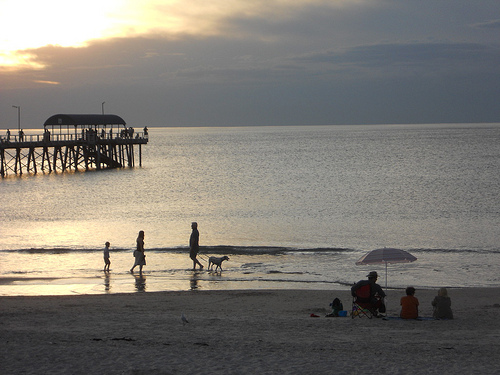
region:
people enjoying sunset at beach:
[73, 151, 461, 347]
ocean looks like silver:
[231, 143, 327, 291]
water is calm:
[238, 144, 477, 261]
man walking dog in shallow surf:
[179, 210, 248, 291]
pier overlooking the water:
[0, 91, 157, 182]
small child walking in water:
[91, 242, 121, 279]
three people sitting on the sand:
[340, 273, 457, 323]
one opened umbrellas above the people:
[342, 232, 453, 314]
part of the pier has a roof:
[47, 110, 127, 137]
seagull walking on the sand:
[171, 306, 206, 333]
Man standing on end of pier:
[140, 116, 154, 146]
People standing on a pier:
[6, 124, 163, 152]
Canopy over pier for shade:
[39, 107, 156, 147]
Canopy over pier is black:
[39, 107, 134, 133]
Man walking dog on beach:
[183, 219, 242, 281]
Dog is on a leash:
[193, 245, 232, 292]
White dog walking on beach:
[202, 253, 230, 275]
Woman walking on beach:
[126, 225, 161, 283]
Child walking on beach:
[91, 235, 123, 282]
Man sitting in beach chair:
[346, 221, 403, 337]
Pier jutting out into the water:
[1, 104, 159, 181]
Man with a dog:
[176, 211, 241, 286]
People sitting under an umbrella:
[292, 234, 467, 334]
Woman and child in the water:
[88, 215, 158, 292]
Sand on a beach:
[41, 293, 318, 365]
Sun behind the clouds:
[4, 5, 206, 112]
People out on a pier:
[50, 114, 160, 157]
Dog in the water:
[202, 249, 242, 279]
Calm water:
[179, 131, 463, 218]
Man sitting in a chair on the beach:
[342, 267, 391, 331]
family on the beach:
[296, 240, 488, 340]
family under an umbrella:
[316, 246, 481, 334]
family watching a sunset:
[301, 239, 461, 330]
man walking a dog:
[182, 216, 233, 291]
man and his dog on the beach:
[174, 216, 244, 293]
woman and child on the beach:
[91, 231, 157, 284]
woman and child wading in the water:
[79, 219, 156, 283]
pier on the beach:
[11, 88, 161, 196]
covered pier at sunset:
[13, 91, 188, 191]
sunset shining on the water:
[21, 194, 96, 318]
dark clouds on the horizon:
[20, 0, 498, 126]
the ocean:
[145, 125, 486, 256]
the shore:
[0, 281, 495, 371]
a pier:
[0, 100, 150, 195]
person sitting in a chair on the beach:
[340, 265, 400, 341]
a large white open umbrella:
[355, 230, 415, 327]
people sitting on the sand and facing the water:
[388, 190, 473, 332]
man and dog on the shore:
[164, 205, 271, 308]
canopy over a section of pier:
[34, 95, 148, 185]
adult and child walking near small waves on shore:
[72, 211, 172, 296]